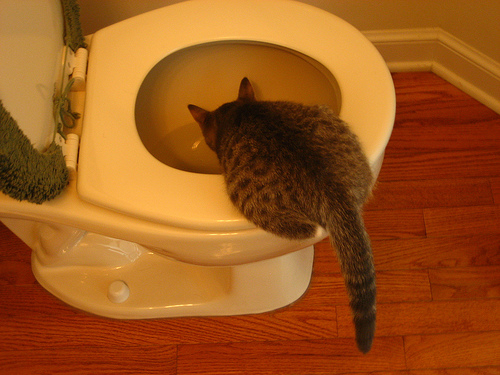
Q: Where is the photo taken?
A: Bathroom.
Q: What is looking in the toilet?
A: Cat.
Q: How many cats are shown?
A: One.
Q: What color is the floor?
A: Brown.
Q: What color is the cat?
A: Gray.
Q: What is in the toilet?
A: Water.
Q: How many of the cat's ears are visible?
A: Two.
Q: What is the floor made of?
A: Wood.